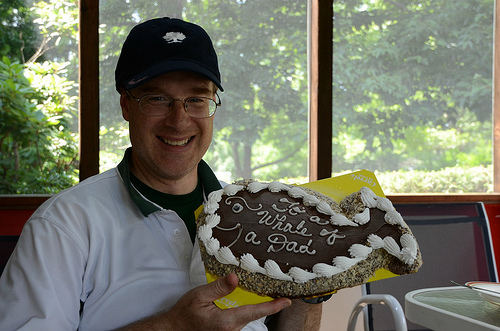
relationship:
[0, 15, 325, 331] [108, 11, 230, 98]
man has hat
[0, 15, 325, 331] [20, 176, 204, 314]
man has white shirt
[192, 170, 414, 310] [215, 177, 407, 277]
plate under cake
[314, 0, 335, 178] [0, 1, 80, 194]
frame between window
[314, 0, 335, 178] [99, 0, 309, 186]
frame between window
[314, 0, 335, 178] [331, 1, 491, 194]
frame between window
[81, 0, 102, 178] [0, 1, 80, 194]
frame between window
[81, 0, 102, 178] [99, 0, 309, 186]
frame between window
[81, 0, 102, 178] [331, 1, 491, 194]
frame between window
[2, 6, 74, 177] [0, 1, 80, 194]
bushes outside window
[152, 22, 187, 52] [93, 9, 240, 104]
logo on hat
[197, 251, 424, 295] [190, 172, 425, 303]
almonds on side of cake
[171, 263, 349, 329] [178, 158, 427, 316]
hands holding cake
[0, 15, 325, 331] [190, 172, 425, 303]
man holding cake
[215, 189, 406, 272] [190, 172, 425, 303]
frosting on cake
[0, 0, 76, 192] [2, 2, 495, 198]
bushes outside window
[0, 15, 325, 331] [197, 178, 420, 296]
man holding cake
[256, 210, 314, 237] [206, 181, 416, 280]
word written in frosting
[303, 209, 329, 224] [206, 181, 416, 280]
word written in frosting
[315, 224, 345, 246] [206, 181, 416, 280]
word written in frosting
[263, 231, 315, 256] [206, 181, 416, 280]
word written in frosting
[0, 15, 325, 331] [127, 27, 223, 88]
man wearing hat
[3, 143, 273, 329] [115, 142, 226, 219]
shirt has collar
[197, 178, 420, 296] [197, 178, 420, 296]
cake shaped like cake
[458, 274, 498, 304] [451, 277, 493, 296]
plate has silverware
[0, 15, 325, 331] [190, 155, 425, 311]
man holding cake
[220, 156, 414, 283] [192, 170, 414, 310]
cake over plate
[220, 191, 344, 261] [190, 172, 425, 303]
decorations on cake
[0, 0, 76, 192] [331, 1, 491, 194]
bushes outside window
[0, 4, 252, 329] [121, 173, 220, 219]
man wearing necklace